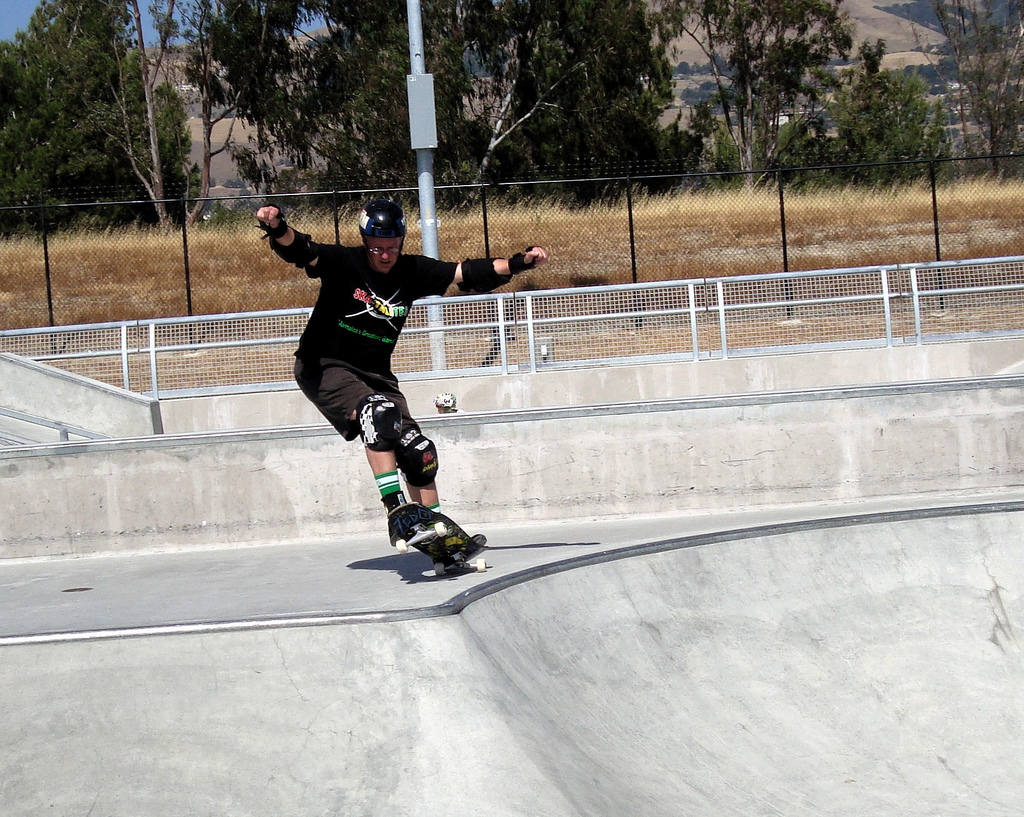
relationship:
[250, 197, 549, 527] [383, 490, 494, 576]
man on a skateboard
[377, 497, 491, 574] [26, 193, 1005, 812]
skateboard in a skate park